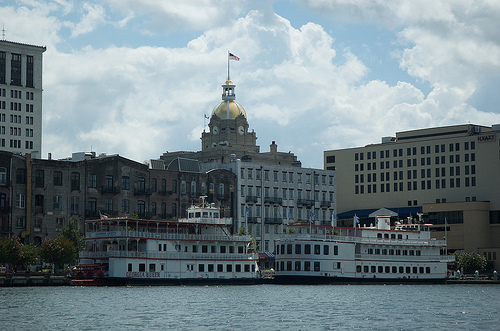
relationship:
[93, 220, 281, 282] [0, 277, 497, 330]
boat on water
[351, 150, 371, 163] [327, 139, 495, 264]
window on building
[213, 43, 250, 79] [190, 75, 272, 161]
flag on building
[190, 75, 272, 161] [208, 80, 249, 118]
building has dome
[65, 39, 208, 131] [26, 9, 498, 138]
cloud in sky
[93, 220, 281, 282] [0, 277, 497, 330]
boat in water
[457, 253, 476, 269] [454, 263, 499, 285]
bush on shorte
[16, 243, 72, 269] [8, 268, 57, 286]
tree on shore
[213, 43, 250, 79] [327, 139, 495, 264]
flag on building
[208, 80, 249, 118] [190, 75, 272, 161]
dome on building